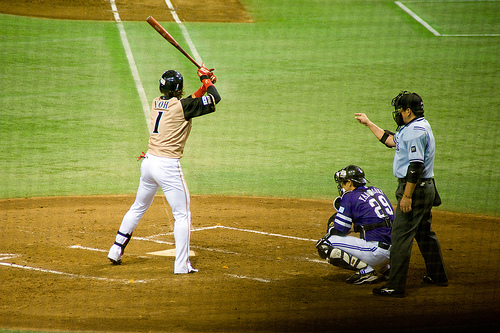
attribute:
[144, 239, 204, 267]
base — home plate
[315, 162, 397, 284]
pitcher — wearing purple, wearing gray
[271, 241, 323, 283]
ground — brown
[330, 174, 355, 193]
mask — face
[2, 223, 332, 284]
lines — white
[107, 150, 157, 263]
leg — lower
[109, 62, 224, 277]
player — baseball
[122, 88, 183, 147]
shirt — back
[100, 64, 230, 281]
player — baseball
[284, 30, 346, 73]
grass — green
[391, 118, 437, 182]
shirt — back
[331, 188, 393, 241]
shirt — back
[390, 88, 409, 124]
mask — face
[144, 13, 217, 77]
bat — red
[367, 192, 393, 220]
number — one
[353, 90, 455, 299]
umpire — baseball, standing, pointing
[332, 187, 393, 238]
jersey — purple